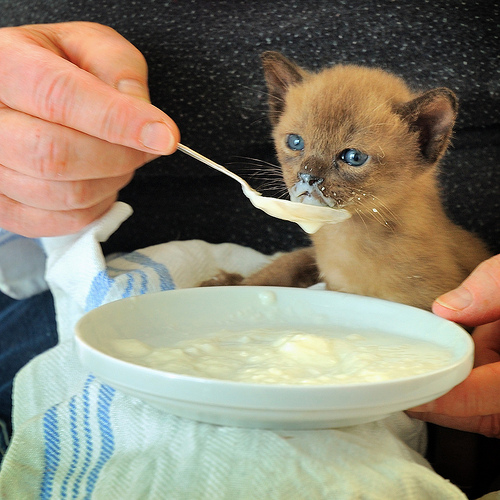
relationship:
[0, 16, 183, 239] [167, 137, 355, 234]
hand holding spoon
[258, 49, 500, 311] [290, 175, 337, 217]
kitten being fed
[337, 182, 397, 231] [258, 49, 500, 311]
whiskers on kitten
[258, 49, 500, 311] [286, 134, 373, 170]
kitten has eyes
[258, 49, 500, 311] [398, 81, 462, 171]
kitten has ear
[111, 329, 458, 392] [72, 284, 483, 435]
food in bowl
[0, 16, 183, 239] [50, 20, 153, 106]
hand has thumb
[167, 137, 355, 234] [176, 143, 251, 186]
spoon has handle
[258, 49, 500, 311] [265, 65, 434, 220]
kitten has head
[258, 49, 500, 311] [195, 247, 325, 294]
kitten has arm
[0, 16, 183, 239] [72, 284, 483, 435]
hand holding bowl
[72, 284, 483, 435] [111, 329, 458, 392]
bowl holding food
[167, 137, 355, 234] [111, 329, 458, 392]
spoon has food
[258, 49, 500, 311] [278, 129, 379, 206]
kitten has face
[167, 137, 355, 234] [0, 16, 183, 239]
spoon in hand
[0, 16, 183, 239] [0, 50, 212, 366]
hand of person